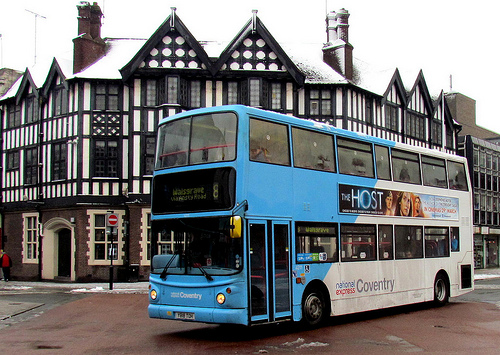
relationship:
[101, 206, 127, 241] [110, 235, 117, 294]
sign on pole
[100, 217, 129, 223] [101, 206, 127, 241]
white dash on sign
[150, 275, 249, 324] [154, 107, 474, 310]
headlights on bus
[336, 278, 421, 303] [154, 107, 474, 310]
name on bus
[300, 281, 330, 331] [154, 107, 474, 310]
black tires on bus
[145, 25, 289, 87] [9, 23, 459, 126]
gables on roof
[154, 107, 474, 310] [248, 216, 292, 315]
bus has door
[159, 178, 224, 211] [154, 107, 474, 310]
electric sign on bus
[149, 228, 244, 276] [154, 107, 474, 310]
windshield on bus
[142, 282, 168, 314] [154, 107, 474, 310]
left headlight on bus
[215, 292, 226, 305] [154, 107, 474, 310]
headlights on bus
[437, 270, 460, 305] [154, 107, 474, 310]
rear tire on bus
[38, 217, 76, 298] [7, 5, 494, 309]
archway on house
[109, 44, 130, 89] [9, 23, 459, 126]
snow on roof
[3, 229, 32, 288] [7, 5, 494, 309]
person by house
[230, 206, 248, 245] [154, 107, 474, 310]
mirror on bus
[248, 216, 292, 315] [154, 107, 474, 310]
door on bus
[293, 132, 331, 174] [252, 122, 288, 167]
people in window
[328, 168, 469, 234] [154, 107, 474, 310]
ad on bus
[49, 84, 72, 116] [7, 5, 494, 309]
window on house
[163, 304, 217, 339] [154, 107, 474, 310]
license on bus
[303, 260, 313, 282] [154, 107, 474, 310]
handicap sticker on bus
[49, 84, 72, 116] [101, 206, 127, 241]
window behind sign